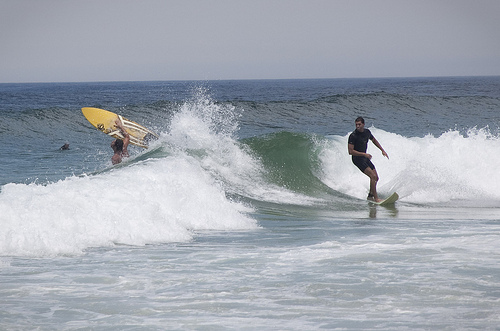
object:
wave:
[0, 80, 499, 261]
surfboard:
[365, 191, 403, 207]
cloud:
[1, 0, 500, 83]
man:
[346, 115, 392, 204]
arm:
[346, 134, 366, 159]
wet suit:
[346, 127, 377, 174]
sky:
[0, 0, 500, 85]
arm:
[366, 128, 384, 152]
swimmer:
[58, 142, 71, 151]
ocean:
[0, 75, 500, 331]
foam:
[0, 82, 499, 257]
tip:
[388, 191, 402, 198]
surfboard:
[79, 105, 161, 149]